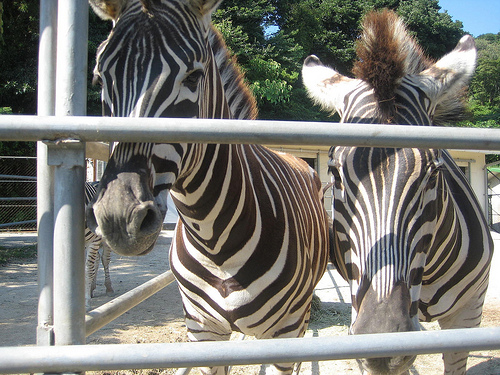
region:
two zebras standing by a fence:
[91, 3, 488, 373]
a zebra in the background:
[83, 183, 116, 305]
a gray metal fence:
[11, 2, 495, 374]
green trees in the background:
[1, 1, 498, 130]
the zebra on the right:
[301, 20, 488, 370]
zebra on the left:
[89, 2, 329, 372]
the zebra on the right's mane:
[357, 18, 419, 115]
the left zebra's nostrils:
[97, 199, 160, 232]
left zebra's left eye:
[183, 73, 203, 95]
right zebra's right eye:
[330, 167, 344, 184]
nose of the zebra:
[76, 163, 192, 263]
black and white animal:
[204, 170, 323, 253]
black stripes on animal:
[194, 167, 341, 275]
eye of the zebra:
[416, 138, 453, 200]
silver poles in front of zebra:
[166, 110, 383, 374]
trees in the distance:
[248, 18, 336, 60]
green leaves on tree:
[263, 3, 346, 54]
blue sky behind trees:
[451, 2, 492, 30]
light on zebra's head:
[124, 78, 169, 105]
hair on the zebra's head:
[341, 31, 431, 111]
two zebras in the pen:
[93, 5, 482, 320]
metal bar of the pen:
[10, 98, 498, 171]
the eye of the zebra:
[84, 62, 118, 97]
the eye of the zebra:
[180, 60, 200, 91]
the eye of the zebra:
[320, 160, 351, 183]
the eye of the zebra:
[402, 159, 443, 184]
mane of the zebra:
[339, 13, 435, 84]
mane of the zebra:
[199, 40, 269, 119]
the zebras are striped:
[88, 6, 498, 356]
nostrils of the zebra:
[77, 182, 177, 261]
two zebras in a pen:
[54, 4, 424, 374]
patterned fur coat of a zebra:
[245, 179, 307, 244]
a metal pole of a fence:
[9, 89, 498, 176]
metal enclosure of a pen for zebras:
[36, 35, 105, 367]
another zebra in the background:
[37, 171, 116, 303]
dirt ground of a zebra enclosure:
[125, 308, 174, 338]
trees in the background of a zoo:
[233, 7, 355, 121]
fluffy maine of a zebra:
[348, 8, 423, 104]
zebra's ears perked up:
[292, 49, 479, 119]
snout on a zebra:
[351, 293, 411, 367]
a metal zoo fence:
[0, 0, 498, 373]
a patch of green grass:
[0, 243, 37, 268]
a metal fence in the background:
[0, 155, 37, 232]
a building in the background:
[85, 141, 110, 182]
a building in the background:
[260, 143, 499, 233]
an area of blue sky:
[258, 0, 498, 40]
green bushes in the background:
[0, 105, 37, 231]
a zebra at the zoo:
[83, 0, 329, 374]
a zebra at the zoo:
[301, 7, 493, 374]